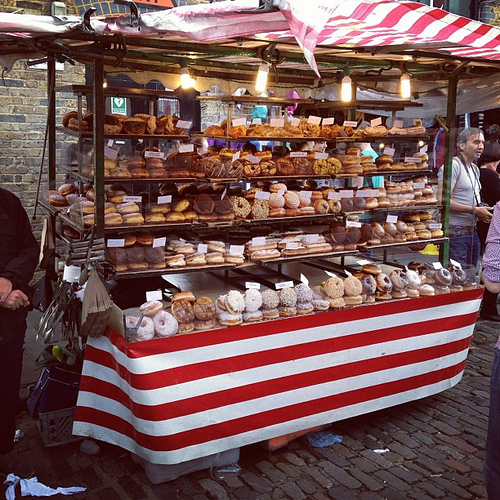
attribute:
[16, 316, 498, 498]
floor — tile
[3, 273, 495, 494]
sidewalk — paved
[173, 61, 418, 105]
lights — hanging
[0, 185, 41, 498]
person — standing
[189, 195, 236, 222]
doughnuts — chocolate, assorted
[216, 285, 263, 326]
doughnuts — sprinkled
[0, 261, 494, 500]
street — cobblestone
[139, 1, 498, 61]
fabric — red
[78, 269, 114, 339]
bags — brown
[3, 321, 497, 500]
road — brick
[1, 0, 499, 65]
covering — red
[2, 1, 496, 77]
awning — red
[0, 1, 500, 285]
building — brick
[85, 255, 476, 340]
table — white